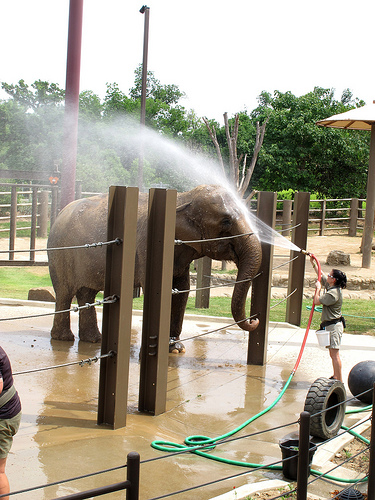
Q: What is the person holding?
A: A hose.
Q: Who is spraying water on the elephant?
A: A woman.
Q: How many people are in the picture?
A: Two.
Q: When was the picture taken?
A: Daytime.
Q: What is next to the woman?
A: A tire.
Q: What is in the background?
A: Trees.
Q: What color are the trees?
A: Green.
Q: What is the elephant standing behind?
A: A fence.